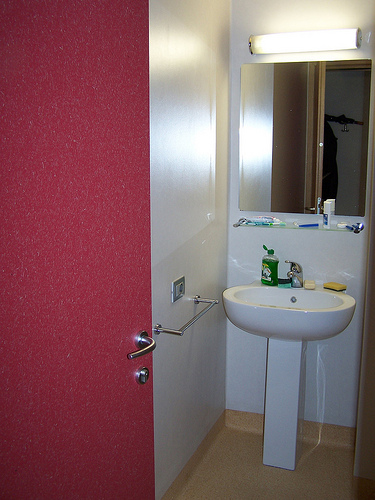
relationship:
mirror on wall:
[238, 64, 369, 225] [229, 34, 238, 282]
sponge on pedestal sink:
[323, 281, 347, 290] [221, 280, 355, 471]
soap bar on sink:
[303, 278, 316, 289] [223, 279, 358, 347]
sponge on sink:
[323, 281, 347, 290] [216, 262, 364, 478]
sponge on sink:
[321, 279, 350, 295] [218, 274, 361, 324]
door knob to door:
[302, 202, 317, 212] [308, 59, 328, 214]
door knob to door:
[318, 203, 325, 212] [308, 59, 328, 214]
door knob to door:
[124, 326, 160, 361] [6, 1, 157, 491]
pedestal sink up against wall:
[221, 280, 355, 471] [147, 2, 370, 498]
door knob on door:
[128, 336, 157, 359] [6, 1, 157, 491]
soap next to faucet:
[259, 242, 278, 287] [282, 253, 304, 293]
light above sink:
[247, 29, 360, 56] [223, 260, 355, 468]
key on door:
[133, 362, 154, 387] [6, 1, 157, 491]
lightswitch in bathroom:
[172, 276, 185, 302] [3, 2, 373, 496]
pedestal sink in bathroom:
[221, 280, 355, 471] [3, 2, 373, 496]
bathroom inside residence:
[24, 25, 373, 416] [2, 3, 372, 498]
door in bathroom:
[6, 1, 157, 491] [3, 2, 373, 496]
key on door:
[136, 366, 149, 385] [6, 1, 157, 491]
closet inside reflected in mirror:
[269, 63, 370, 221] [238, 64, 369, 225]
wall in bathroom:
[149, 0, 229, 498] [3, 2, 373, 496]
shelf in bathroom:
[233, 220, 364, 231] [3, 2, 373, 496]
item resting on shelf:
[319, 194, 338, 230] [232, 221, 356, 233]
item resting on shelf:
[291, 216, 322, 231] [232, 221, 356, 233]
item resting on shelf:
[233, 216, 286, 228] [232, 221, 356, 233]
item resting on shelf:
[242, 219, 274, 229] [232, 221, 356, 233]